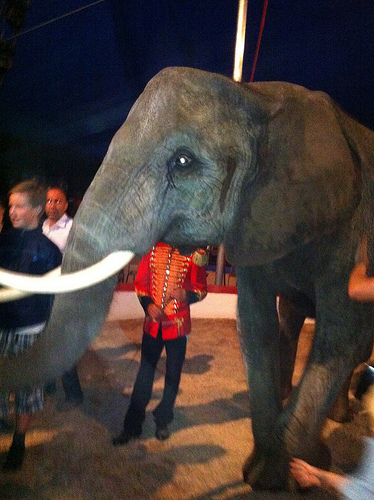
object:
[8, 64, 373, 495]
elephant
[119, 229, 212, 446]
man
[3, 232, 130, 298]
tusks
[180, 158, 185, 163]
light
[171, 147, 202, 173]
eye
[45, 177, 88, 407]
man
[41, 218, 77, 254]
white shirt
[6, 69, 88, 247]
wall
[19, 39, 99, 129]
boarder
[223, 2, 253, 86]
pole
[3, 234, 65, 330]
jacket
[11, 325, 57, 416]
shorts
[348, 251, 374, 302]
person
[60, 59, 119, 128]
circus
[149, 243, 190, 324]
orange jacket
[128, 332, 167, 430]
pants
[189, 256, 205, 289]
arms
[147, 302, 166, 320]
hands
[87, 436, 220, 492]
dirt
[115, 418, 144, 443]
shoes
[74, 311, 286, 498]
ground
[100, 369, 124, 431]
shadows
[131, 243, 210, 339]
red coat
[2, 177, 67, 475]
boy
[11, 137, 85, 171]
dark